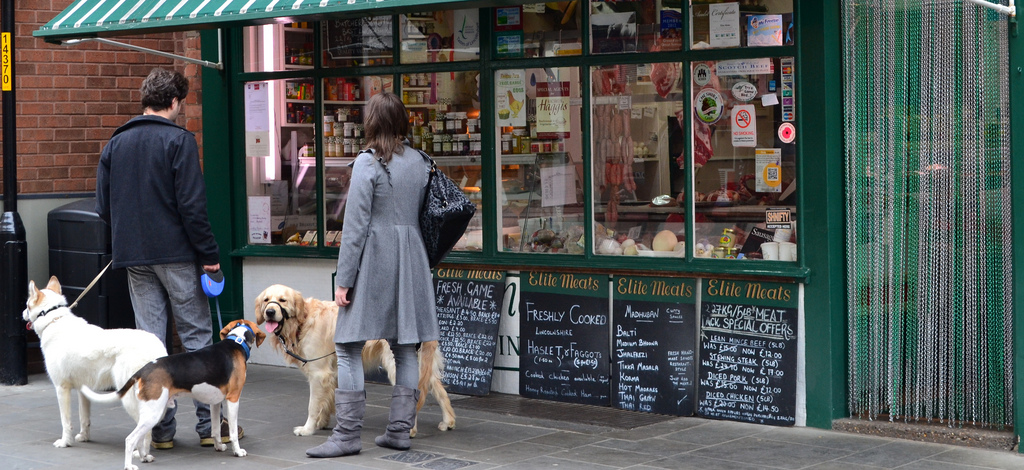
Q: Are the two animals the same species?
A: Yes, all the animals are dogs.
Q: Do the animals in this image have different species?
A: No, all the animals are dogs.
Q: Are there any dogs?
A: Yes, there is a dog.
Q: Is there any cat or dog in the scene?
A: Yes, there is a dog.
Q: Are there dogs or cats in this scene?
A: Yes, there is a dog.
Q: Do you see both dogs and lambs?
A: No, there is a dog but no lambs.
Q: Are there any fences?
A: No, there are no fences.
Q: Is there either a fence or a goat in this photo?
A: No, there are no fences or goats.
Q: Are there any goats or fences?
A: No, there are no fences or goats.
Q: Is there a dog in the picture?
A: Yes, there is a dog.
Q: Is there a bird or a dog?
A: Yes, there is a dog.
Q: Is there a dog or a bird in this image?
A: Yes, there is a dog.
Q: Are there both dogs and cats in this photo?
A: No, there is a dog but no cats.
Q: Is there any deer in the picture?
A: No, there is no deer.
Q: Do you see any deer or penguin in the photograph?
A: No, there are no deer or penguins.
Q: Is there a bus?
A: No, there are no buses.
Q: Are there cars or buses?
A: No, there are no buses or cars.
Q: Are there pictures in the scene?
A: No, there are no pictures.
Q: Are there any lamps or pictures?
A: No, there are no pictures or lamps.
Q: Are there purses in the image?
A: Yes, there is a purse.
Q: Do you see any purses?
A: Yes, there is a purse.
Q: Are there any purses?
A: Yes, there is a purse.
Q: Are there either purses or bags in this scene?
A: Yes, there is a purse.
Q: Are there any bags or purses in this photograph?
A: Yes, there is a purse.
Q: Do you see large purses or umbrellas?
A: Yes, there is a large purse.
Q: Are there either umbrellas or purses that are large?
A: Yes, the purse is large.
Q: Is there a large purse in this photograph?
A: Yes, there is a large purse.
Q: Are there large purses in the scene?
A: Yes, there is a large purse.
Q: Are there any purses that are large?
A: Yes, there is a purse that is large.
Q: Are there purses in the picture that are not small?
A: Yes, there is a large purse.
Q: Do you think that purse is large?
A: Yes, the purse is large.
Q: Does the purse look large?
A: Yes, the purse is large.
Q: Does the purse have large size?
A: Yes, the purse is large.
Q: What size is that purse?
A: The purse is large.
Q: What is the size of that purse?
A: The purse is large.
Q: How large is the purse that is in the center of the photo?
A: The purse is large.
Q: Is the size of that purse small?
A: No, the purse is large.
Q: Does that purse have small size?
A: No, the purse is large.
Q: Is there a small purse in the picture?
A: No, there is a purse but it is large.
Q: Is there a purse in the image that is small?
A: No, there is a purse but it is large.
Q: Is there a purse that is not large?
A: No, there is a purse but it is large.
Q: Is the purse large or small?
A: The purse is large.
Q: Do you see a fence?
A: No, there are no fences.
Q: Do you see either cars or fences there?
A: No, there are no fences or cars.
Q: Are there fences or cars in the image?
A: No, there are no fences or cars.